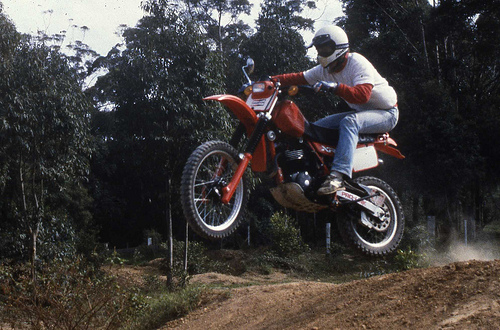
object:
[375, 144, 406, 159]
fender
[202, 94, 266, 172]
fender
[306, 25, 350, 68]
helmet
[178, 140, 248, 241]
tire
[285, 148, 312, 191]
engine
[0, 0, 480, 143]
sky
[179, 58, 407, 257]
bike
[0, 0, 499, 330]
photo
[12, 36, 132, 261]
branch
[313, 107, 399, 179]
jeans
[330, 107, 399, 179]
legs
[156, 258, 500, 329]
dirt ramp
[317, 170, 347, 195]
foot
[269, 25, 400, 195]
man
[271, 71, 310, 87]
sleeve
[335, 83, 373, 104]
sleeve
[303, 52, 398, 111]
shirt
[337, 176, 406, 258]
rear wheel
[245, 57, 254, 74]
mirror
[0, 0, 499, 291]
trees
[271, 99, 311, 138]
tank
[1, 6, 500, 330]
forrest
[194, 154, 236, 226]
spoke